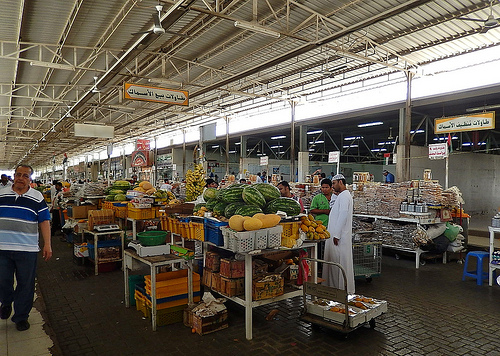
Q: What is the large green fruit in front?
A: Watermelon.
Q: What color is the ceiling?
A: White.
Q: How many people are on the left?
A: One.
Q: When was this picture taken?
A: Daytime.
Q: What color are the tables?
A: White.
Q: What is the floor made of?
A: Brick.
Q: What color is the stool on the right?
A: Blue.